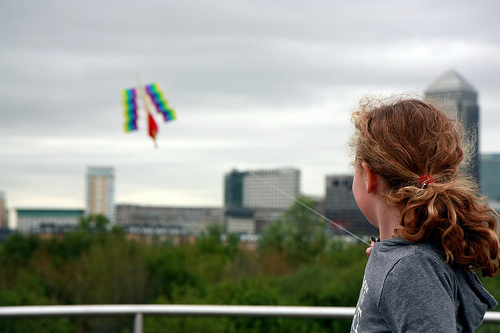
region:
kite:
[116, 79, 186, 140]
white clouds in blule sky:
[33, 76, 68, 121]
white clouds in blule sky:
[84, 14, 138, 46]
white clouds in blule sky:
[188, 28, 242, 76]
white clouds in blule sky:
[215, 109, 272, 151]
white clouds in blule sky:
[254, 37, 295, 96]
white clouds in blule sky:
[303, 31, 358, 89]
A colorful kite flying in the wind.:
[115, 75, 177, 150]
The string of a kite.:
[238, 163, 368, 245]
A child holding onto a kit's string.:
[344, 98, 496, 330]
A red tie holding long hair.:
[416, 173, 437, 189]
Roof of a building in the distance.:
[423, 64, 479, 96]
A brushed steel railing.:
[0, 300, 355, 330]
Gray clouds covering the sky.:
[3, 2, 493, 188]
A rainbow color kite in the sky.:
[123, 80, 178, 147]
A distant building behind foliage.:
[85, 162, 115, 232]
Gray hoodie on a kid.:
[351, 236, 496, 331]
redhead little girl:
[346, 96, 497, 331]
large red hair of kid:
[351, 96, 495, 270]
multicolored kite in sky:
[120, 81, 175, 153]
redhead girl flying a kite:
[340, 102, 497, 329]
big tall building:
[424, 66, 481, 187]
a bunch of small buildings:
[1, 160, 365, 245]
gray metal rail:
[3, 302, 498, 328]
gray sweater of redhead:
[348, 240, 494, 331]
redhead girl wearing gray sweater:
[345, 98, 495, 330]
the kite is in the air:
[120, 80, 170, 150]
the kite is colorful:
[118, 72, 178, 150]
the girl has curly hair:
[350, 90, 495, 277]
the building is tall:
[421, 66, 479, 189]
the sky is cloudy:
[2, 0, 499, 205]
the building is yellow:
[86, 163, 113, 223]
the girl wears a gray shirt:
[348, 230, 492, 330]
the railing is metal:
[1, 306, 356, 328]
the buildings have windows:
[221, 166, 299, 208]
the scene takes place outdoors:
[0, 0, 498, 332]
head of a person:
[327, 92, 465, 250]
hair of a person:
[385, 76, 456, 166]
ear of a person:
[348, 153, 382, 195]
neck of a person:
[354, 213, 422, 257]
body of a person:
[355, 233, 477, 330]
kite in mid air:
[70, 78, 201, 180]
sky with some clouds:
[245, 56, 316, 114]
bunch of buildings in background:
[14, 133, 358, 244]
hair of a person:
[448, 202, 485, 249]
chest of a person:
[348, 261, 383, 322]